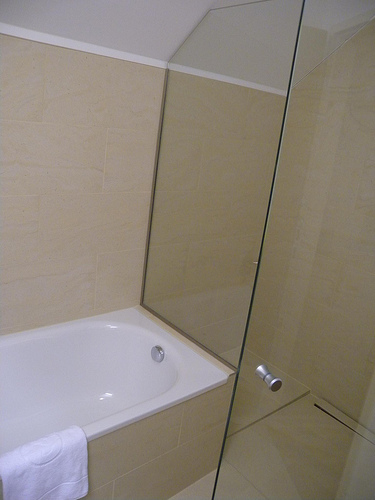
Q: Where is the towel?
A: Bathtub.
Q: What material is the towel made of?
A: Cotton.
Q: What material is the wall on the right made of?
A: Glass.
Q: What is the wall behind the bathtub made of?
A: Tiles.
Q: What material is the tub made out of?
A: Ceramic.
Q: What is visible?
A: Tub.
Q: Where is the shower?
A: By tub.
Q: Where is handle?
A: Shower door.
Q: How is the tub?
A: Deep.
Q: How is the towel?
A: Hanging.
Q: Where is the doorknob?
A: On the mirror.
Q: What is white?
A: Tub.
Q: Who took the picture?
A: Man.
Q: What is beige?
A: Wall.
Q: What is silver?
A: Knob.